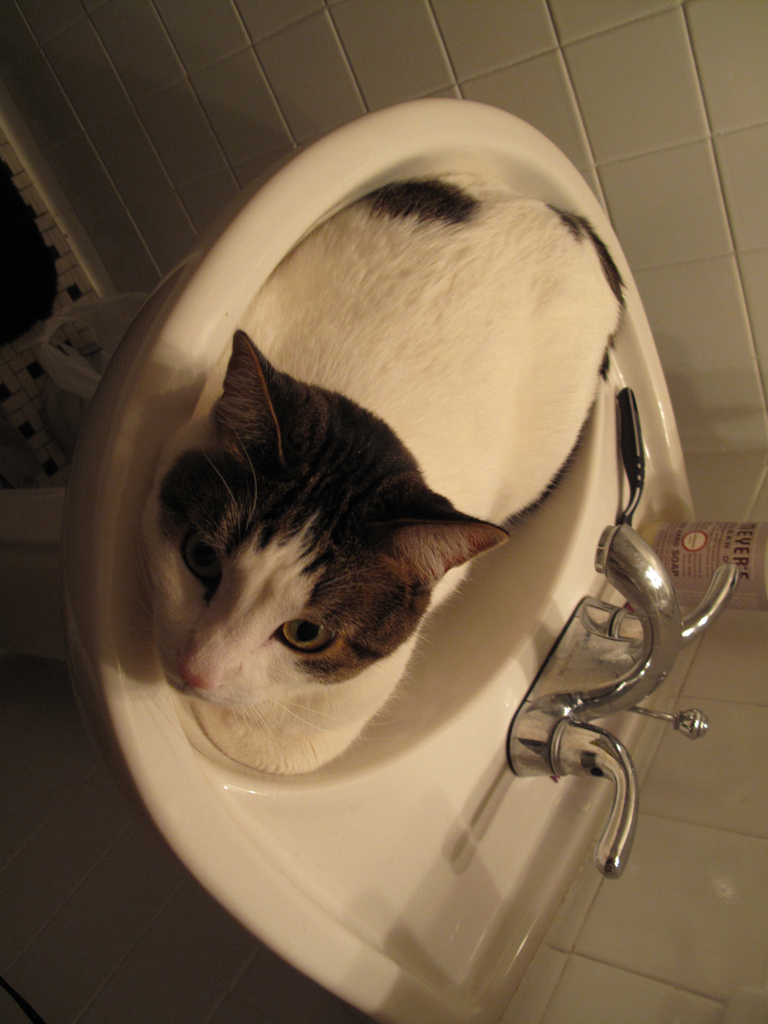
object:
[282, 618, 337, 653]
eyes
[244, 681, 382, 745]
whisker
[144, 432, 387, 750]
cat's face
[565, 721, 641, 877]
handle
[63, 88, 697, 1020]
basin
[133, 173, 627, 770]
cat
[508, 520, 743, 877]
faucet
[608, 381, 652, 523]
handle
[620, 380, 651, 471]
line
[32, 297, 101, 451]
plastic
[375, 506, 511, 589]
cat's ear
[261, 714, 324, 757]
thin-long whiskers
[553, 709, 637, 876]
faucet switch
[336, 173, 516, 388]
white hair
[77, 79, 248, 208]
tiles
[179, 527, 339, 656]
two eyes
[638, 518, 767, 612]
bottle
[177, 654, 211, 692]
cat-pink nose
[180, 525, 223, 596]
domestic-cat's eye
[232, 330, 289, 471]
cat ear